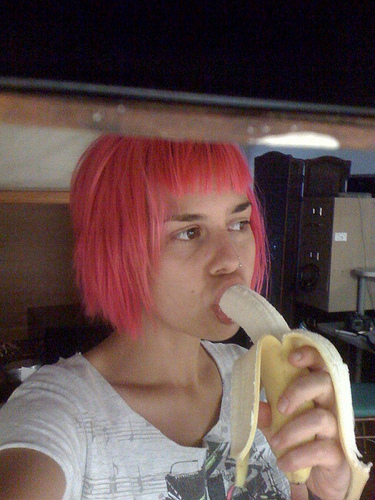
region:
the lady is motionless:
[53, 148, 220, 490]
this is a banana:
[213, 281, 281, 343]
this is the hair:
[70, 163, 150, 317]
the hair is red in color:
[78, 196, 155, 319]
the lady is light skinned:
[141, 352, 198, 410]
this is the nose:
[214, 245, 242, 272]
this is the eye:
[172, 224, 202, 242]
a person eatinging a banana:
[75, 146, 347, 491]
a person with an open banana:
[48, 204, 282, 488]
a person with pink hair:
[57, 209, 251, 342]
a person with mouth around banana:
[67, 175, 265, 382]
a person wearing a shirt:
[83, 220, 311, 486]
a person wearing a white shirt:
[22, 245, 367, 499]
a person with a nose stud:
[76, 211, 271, 354]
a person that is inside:
[63, 194, 374, 495]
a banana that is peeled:
[201, 296, 353, 448]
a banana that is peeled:
[221, 276, 365, 450]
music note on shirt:
[87, 419, 99, 443]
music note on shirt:
[102, 424, 113, 444]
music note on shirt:
[126, 412, 134, 443]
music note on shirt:
[110, 460, 120, 480]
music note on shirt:
[109, 481, 119, 492]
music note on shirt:
[135, 464, 143, 483]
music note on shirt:
[136, 480, 142, 495]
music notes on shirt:
[107, 457, 119, 494]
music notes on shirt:
[135, 466, 146, 493]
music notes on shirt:
[88, 415, 136, 446]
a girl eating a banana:
[22, 107, 365, 471]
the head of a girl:
[63, 136, 269, 332]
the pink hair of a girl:
[63, 188, 149, 253]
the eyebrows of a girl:
[167, 203, 254, 216]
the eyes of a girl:
[160, 203, 261, 243]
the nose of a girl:
[202, 230, 242, 278]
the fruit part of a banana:
[222, 278, 280, 343]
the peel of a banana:
[217, 346, 273, 446]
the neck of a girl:
[75, 327, 201, 385]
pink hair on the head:
[59, 123, 288, 352]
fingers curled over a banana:
[244, 341, 341, 483]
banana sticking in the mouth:
[204, 275, 373, 494]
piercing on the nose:
[232, 254, 246, 271]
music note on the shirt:
[120, 417, 145, 447]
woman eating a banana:
[1, 125, 373, 498]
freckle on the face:
[185, 285, 197, 297]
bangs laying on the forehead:
[150, 150, 257, 200]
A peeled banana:
[223, 290, 363, 490]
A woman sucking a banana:
[76, 128, 274, 338]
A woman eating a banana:
[0, 132, 371, 496]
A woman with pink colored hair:
[0, 124, 371, 372]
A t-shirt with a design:
[0, 329, 315, 498]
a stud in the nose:
[237, 262, 239, 271]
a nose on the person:
[207, 221, 248, 294]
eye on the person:
[172, 226, 200, 236]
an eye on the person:
[232, 220, 250, 235]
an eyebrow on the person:
[228, 196, 245, 210]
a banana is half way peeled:
[196, 276, 373, 432]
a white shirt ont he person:
[14, 340, 173, 489]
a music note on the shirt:
[127, 413, 131, 447]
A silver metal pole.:
[352, 273, 363, 316]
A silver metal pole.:
[353, 338, 358, 385]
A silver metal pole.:
[345, 415, 373, 425]